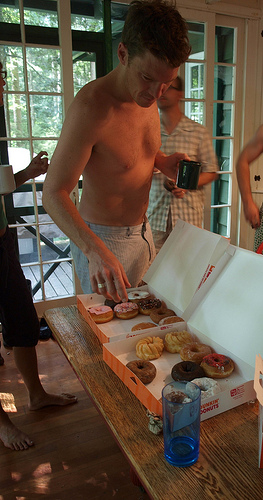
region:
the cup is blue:
[162, 380, 198, 465]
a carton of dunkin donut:
[103, 325, 259, 418]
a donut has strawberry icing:
[86, 302, 134, 323]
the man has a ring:
[99, 282, 105, 289]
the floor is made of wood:
[0, 341, 149, 497]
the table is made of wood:
[44, 302, 261, 498]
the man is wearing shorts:
[0, 234, 40, 358]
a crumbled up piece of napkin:
[145, 407, 161, 433]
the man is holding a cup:
[178, 159, 200, 191]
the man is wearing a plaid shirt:
[147, 116, 217, 227]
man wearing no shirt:
[78, 131, 163, 200]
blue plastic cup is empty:
[156, 392, 210, 460]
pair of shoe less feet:
[7, 390, 69, 453]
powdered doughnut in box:
[189, 377, 216, 395]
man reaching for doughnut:
[90, 263, 127, 301]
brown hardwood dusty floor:
[64, 433, 101, 484]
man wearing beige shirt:
[150, 195, 205, 227]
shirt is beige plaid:
[163, 198, 183, 213]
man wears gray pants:
[122, 236, 143, 269]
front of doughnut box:
[134, 379, 158, 412]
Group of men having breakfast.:
[0, 1, 258, 493]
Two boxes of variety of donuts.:
[73, 283, 255, 412]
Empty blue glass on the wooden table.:
[160, 377, 201, 467]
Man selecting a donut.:
[40, 3, 234, 379]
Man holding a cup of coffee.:
[93, 3, 200, 193]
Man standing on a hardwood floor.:
[0, 60, 75, 463]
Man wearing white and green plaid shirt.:
[160, 107, 216, 226]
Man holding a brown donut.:
[160, 175, 178, 200]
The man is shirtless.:
[57, 107, 169, 236]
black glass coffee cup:
[173, 157, 203, 191]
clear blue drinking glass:
[158, 377, 202, 467]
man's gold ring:
[94, 281, 107, 291]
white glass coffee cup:
[0, 163, 17, 196]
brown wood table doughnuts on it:
[41, 302, 261, 498]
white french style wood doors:
[1, 0, 248, 329]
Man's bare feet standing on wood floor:
[0, 390, 79, 451]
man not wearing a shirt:
[40, 0, 196, 229]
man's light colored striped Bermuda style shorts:
[66, 213, 158, 297]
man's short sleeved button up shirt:
[142, 110, 218, 232]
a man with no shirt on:
[40, 1, 216, 226]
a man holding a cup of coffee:
[55, 1, 212, 195]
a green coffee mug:
[173, 157, 201, 187]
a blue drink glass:
[156, 380, 208, 465]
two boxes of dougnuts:
[83, 269, 246, 425]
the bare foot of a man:
[23, 378, 78, 414]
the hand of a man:
[86, 260, 131, 303]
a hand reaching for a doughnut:
[73, 229, 168, 386]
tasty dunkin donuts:
[80, 275, 186, 338]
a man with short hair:
[118, 0, 190, 112]